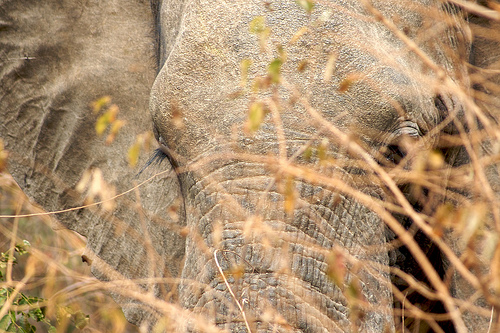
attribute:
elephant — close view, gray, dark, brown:
[81, 28, 479, 324]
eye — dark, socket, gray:
[375, 112, 439, 163]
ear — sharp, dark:
[4, 49, 161, 222]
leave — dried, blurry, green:
[23, 258, 100, 323]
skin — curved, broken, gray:
[191, 141, 312, 239]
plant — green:
[7, 286, 48, 333]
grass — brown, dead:
[408, 179, 477, 289]